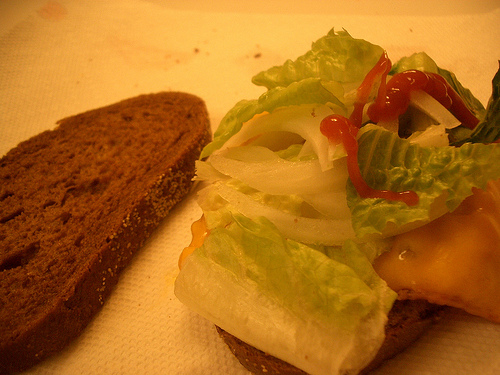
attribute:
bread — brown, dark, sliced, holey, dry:
[2, 70, 214, 356]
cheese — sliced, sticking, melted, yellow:
[386, 194, 499, 313]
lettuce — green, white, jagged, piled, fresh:
[183, 28, 483, 369]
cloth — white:
[5, 7, 275, 117]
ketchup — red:
[334, 62, 481, 202]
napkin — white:
[336, 4, 497, 67]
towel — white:
[5, 3, 500, 86]